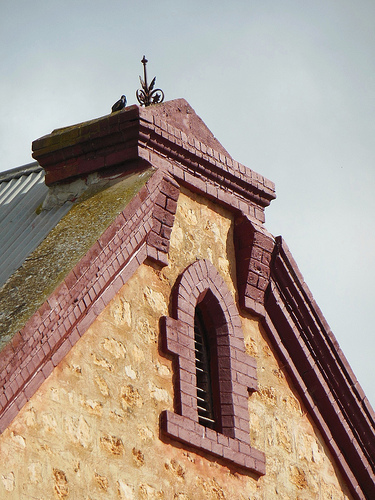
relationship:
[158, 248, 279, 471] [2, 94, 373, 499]
window on building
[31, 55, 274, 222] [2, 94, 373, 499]
peak of a building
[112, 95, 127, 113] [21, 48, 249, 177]
bird on a roof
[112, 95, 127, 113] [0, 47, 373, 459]
bird on a roof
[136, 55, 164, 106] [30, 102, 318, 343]
decoration on a roof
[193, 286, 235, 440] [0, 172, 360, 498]
window in wall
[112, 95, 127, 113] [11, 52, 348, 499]
bird on building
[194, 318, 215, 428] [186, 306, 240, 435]
grid in window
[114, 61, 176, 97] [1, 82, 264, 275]
rod on top of roof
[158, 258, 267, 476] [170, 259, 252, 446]
area around window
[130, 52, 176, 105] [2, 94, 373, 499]
decoration at top of building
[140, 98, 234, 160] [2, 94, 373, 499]
peak of building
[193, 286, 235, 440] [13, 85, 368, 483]
window on building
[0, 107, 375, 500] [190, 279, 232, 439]
brick around window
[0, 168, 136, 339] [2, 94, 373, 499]
roof of building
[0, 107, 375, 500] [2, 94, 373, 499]
brick on top of building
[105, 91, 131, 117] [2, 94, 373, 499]
bird on top of building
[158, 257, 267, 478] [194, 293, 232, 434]
brick around window opening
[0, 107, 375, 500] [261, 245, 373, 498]
brick on eave